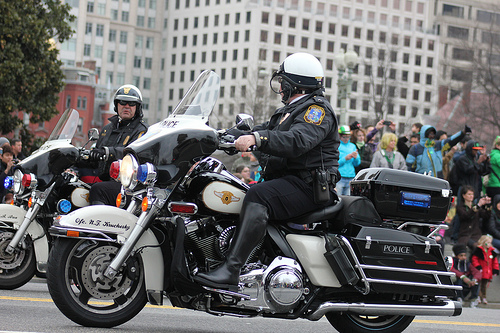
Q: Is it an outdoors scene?
A: Yes, it is outdoors.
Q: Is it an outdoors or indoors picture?
A: It is outdoors.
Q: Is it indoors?
A: No, it is outdoors.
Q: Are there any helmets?
A: Yes, there is a helmet.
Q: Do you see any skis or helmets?
A: Yes, there is a helmet.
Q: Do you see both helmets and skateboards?
A: No, there is a helmet but no skateboards.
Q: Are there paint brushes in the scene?
A: No, there are no paint brushes.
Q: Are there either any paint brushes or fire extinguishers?
A: No, there are no paint brushes or fire extinguishers.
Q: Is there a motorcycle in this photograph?
A: Yes, there is a motorcycle.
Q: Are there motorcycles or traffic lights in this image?
A: Yes, there is a motorcycle.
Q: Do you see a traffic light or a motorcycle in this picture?
A: Yes, there is a motorcycle.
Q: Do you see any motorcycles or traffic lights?
A: Yes, there is a motorcycle.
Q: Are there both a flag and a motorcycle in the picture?
A: No, there is a motorcycle but no flags.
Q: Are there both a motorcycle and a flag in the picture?
A: No, there is a motorcycle but no flags.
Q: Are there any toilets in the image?
A: No, there are no toilets.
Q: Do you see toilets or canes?
A: No, there are no toilets or canes.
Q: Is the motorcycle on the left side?
A: Yes, the motorcycle is on the left of the image.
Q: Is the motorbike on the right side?
A: No, the motorbike is on the left of the image.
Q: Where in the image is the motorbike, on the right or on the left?
A: The motorbike is on the left of the image.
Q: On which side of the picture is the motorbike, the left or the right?
A: The motorbike is on the left of the image.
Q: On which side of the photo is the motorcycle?
A: The motorcycle is on the left of the image.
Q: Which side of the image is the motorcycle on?
A: The motorcycle is on the left of the image.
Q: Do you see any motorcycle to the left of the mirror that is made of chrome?
A: Yes, there is a motorcycle to the left of the mirror.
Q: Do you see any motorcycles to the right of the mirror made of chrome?
A: No, the motorcycle is to the left of the mirror.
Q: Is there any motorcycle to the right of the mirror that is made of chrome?
A: No, the motorcycle is to the left of the mirror.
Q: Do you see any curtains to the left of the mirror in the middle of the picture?
A: No, there is a motorcycle to the left of the mirror.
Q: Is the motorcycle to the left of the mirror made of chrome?
A: Yes, the motorcycle is to the left of the mirror.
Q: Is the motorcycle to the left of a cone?
A: No, the motorcycle is to the left of the mirror.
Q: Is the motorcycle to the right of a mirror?
A: No, the motorcycle is to the left of a mirror.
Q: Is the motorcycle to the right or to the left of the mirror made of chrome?
A: The motorcycle is to the left of the mirror.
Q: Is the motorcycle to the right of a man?
A: No, the motorcycle is to the left of a man.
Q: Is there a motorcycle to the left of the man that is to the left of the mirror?
A: Yes, there is a motorcycle to the left of the man.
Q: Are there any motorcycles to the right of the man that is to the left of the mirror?
A: No, the motorcycle is to the left of the man.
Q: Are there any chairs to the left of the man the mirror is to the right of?
A: No, there is a motorcycle to the left of the man.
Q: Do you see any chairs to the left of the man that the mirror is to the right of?
A: No, there is a motorcycle to the left of the man.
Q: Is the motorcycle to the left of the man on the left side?
A: Yes, the motorcycle is to the left of the man.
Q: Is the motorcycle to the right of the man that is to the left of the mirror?
A: No, the motorcycle is to the left of the man.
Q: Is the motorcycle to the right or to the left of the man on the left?
A: The motorcycle is to the left of the man.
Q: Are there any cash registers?
A: No, there are no cash registers.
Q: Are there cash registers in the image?
A: No, there are no cash registers.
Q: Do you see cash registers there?
A: No, there are no cash registers.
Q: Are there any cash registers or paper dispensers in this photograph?
A: No, there are no cash registers or paper dispensers.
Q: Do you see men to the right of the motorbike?
A: Yes, there is a man to the right of the motorbike.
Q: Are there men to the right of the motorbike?
A: Yes, there is a man to the right of the motorbike.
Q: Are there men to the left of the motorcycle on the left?
A: No, the man is to the right of the motorbike.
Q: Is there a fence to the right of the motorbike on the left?
A: No, there is a man to the right of the motorcycle.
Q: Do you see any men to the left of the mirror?
A: Yes, there is a man to the left of the mirror.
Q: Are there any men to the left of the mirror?
A: Yes, there is a man to the left of the mirror.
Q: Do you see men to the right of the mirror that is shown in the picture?
A: No, the man is to the left of the mirror.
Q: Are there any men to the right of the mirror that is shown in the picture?
A: No, the man is to the left of the mirror.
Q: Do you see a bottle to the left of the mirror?
A: No, there is a man to the left of the mirror.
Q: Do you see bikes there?
A: Yes, there is a bike.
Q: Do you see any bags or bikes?
A: Yes, there is a bike.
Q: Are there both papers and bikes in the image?
A: No, there is a bike but no papers.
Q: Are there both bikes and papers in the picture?
A: No, there is a bike but no papers.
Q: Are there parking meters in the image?
A: No, there are no parking meters.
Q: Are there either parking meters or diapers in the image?
A: No, there are no parking meters or diapers.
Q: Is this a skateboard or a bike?
A: This is a bike.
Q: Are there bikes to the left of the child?
A: Yes, there is a bike to the left of the child.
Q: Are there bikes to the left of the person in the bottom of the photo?
A: Yes, there is a bike to the left of the child.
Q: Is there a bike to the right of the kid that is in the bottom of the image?
A: No, the bike is to the left of the kid.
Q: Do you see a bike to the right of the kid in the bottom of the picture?
A: No, the bike is to the left of the kid.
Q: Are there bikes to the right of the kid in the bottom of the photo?
A: No, the bike is to the left of the kid.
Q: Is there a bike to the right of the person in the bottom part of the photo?
A: No, the bike is to the left of the kid.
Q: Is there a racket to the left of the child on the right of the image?
A: No, there is a bike to the left of the kid.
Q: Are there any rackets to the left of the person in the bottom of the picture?
A: No, there is a bike to the left of the kid.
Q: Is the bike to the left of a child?
A: Yes, the bike is to the left of a child.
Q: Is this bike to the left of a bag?
A: No, the bike is to the left of a child.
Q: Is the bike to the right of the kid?
A: No, the bike is to the left of the kid.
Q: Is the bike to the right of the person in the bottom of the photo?
A: No, the bike is to the left of the kid.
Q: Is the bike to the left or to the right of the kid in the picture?
A: The bike is to the left of the kid.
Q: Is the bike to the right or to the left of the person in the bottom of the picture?
A: The bike is to the left of the kid.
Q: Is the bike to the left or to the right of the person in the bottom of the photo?
A: The bike is to the left of the kid.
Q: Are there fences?
A: No, there are no fences.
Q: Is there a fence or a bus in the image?
A: No, there are no fences or buses.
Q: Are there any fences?
A: No, there are no fences.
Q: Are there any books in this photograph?
A: No, there are no books.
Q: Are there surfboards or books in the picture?
A: No, there are no books or surfboards.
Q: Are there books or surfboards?
A: No, there are no books or surfboards.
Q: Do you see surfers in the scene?
A: No, there are no surfers.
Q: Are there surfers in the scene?
A: No, there are no surfers.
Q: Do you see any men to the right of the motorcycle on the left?
A: Yes, there is a man to the right of the motorbike.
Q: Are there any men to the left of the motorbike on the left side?
A: No, the man is to the right of the motorcycle.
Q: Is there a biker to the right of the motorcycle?
A: No, there is a man to the right of the motorcycle.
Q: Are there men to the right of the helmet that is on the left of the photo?
A: Yes, there is a man to the right of the helmet.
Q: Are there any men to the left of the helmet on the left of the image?
A: No, the man is to the right of the helmet.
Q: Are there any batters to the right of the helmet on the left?
A: No, there is a man to the right of the helmet.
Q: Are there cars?
A: No, there are no cars.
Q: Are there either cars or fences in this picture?
A: No, there are no cars or fences.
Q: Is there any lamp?
A: No, there are no lamps.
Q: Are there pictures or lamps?
A: No, there are no lamps or pictures.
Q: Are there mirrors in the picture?
A: Yes, there is a mirror.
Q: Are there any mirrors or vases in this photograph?
A: Yes, there is a mirror.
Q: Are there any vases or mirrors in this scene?
A: Yes, there is a mirror.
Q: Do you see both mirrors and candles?
A: No, there is a mirror but no candles.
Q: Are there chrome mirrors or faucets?
A: Yes, there is a chrome mirror.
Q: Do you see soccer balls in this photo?
A: No, there are no soccer balls.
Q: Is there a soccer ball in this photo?
A: No, there are no soccer balls.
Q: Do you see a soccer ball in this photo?
A: No, there are no soccer balls.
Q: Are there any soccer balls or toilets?
A: No, there are no soccer balls or toilets.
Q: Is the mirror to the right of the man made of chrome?
A: Yes, the mirror is made of chrome.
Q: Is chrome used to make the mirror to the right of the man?
A: Yes, the mirror is made of chrome.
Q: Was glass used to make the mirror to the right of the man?
A: No, the mirror is made of chrome.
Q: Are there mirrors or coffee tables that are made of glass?
A: No, there is a mirror but it is made of chrome.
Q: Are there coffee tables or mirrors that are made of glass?
A: No, there is a mirror but it is made of chrome.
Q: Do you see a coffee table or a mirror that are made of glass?
A: No, there is a mirror but it is made of chrome.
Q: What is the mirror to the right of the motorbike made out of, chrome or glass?
A: The mirror is made of chrome.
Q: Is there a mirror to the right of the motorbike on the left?
A: Yes, there is a mirror to the right of the motorbike.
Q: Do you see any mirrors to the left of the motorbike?
A: No, the mirror is to the right of the motorbike.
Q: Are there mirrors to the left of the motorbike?
A: No, the mirror is to the right of the motorbike.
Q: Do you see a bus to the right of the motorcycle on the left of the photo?
A: No, there is a mirror to the right of the motorcycle.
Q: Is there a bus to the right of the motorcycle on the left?
A: No, there is a mirror to the right of the motorcycle.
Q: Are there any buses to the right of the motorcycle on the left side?
A: No, there is a mirror to the right of the motorcycle.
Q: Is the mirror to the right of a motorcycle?
A: Yes, the mirror is to the right of a motorcycle.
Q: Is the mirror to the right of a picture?
A: No, the mirror is to the right of a motorcycle.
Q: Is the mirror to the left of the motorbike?
A: No, the mirror is to the right of the motorbike.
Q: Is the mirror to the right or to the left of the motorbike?
A: The mirror is to the right of the motorbike.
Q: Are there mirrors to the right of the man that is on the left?
A: Yes, there is a mirror to the right of the man.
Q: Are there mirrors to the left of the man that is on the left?
A: No, the mirror is to the right of the man.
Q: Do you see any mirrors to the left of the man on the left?
A: No, the mirror is to the right of the man.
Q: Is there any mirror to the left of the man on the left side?
A: No, the mirror is to the right of the man.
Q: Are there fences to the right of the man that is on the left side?
A: No, there is a mirror to the right of the man.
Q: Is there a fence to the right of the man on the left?
A: No, there is a mirror to the right of the man.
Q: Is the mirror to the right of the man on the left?
A: Yes, the mirror is to the right of the man.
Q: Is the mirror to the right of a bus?
A: No, the mirror is to the right of the man.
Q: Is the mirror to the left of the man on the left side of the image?
A: No, the mirror is to the right of the man.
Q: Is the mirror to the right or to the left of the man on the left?
A: The mirror is to the right of the man.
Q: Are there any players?
A: No, there are no players.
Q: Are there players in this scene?
A: No, there are no players.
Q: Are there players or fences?
A: No, there are no players or fences.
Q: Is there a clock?
A: No, there are no clocks.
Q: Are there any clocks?
A: No, there are no clocks.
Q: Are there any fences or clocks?
A: No, there are no clocks or fences.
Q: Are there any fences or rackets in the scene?
A: No, there are no fences or rackets.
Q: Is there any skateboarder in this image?
A: No, there are no skateboarders.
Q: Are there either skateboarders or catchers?
A: No, there are no skateboarders or catchers.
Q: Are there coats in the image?
A: Yes, there is a coat.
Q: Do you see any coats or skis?
A: Yes, there is a coat.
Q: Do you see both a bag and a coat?
A: No, there is a coat but no bags.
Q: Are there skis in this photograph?
A: No, there are no skis.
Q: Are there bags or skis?
A: No, there are no skis or bags.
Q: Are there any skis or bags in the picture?
A: No, there are no skis or bags.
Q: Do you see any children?
A: Yes, there is a child.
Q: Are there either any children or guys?
A: Yes, there is a child.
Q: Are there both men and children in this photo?
A: Yes, there are both a child and a man.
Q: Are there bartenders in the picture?
A: No, there are no bartenders.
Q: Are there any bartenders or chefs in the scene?
A: No, there are no bartenders or chefs.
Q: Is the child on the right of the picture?
A: Yes, the child is on the right of the image.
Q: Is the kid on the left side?
A: No, the kid is on the right of the image.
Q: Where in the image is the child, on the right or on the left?
A: The child is on the right of the image.